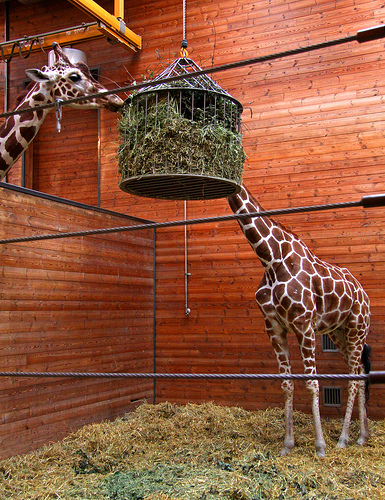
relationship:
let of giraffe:
[259, 335, 336, 466] [0, 34, 159, 191]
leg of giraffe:
[259, 335, 336, 466] [0, 34, 159, 191]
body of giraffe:
[234, 197, 384, 355] [0, 34, 159, 191]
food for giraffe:
[108, 87, 289, 190] [0, 34, 159, 191]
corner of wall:
[113, 206, 191, 414] [0, 191, 156, 401]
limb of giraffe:
[259, 335, 336, 466] [0, 34, 159, 191]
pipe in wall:
[0, 38, 31, 99] [0, 191, 156, 401]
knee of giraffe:
[261, 343, 304, 408] [0, 34, 159, 191]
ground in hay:
[111, 396, 332, 496] [133, 409, 271, 499]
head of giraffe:
[8, 34, 157, 132] [0, 34, 159, 191]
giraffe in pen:
[0, 34, 159, 191] [17, 17, 377, 437]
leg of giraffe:
[257, 294, 368, 429] [0, 34, 159, 191]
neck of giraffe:
[0, 94, 65, 174] [0, 34, 159, 191]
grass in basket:
[108, 87, 289, 190] [107, 51, 262, 209]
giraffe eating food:
[0, 34, 159, 191] [117, 75, 245, 179]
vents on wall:
[19, 119, 121, 195] [0, 191, 156, 401]